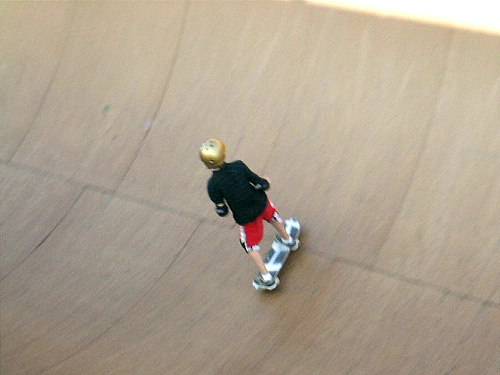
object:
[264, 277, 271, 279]
white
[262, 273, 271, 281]
sock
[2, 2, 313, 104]
ramp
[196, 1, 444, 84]
ramp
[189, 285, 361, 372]
ramp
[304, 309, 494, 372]
ramp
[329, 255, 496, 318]
line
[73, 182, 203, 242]
line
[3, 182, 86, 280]
line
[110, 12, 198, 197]
line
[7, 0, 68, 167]
line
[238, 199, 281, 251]
shorts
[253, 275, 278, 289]
shoe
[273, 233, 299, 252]
shoe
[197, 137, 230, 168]
helmet